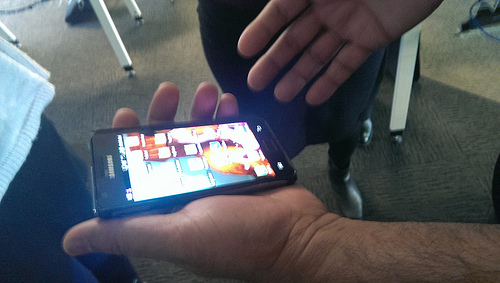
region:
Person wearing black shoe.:
[313, 148, 371, 228]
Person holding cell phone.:
[86, 110, 268, 218]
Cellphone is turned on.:
[84, 102, 281, 191]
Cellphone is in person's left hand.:
[95, 125, 284, 216]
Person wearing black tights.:
[331, 128, 355, 181]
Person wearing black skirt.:
[249, 58, 379, 126]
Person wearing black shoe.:
[357, 112, 381, 142]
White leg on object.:
[67, 18, 138, 80]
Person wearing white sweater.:
[6, 53, 65, 165]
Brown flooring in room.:
[47, 58, 147, 135]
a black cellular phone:
[91, 115, 296, 215]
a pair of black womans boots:
[327, 155, 365, 222]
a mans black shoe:
[357, 116, 373, 147]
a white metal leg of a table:
[89, 0, 142, 77]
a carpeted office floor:
[417, 63, 497, 216]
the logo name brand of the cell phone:
[104, 152, 116, 182]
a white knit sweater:
[0, 34, 53, 202]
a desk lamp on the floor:
[457, 0, 499, 40]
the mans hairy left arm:
[313, 215, 499, 281]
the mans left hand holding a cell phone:
[63, 81, 323, 281]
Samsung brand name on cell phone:
[101, 150, 116, 181]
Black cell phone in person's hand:
[81, 117, 298, 224]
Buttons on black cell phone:
[249, 119, 290, 171]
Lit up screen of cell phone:
[113, 119, 280, 201]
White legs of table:
[0, 0, 167, 83]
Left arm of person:
[300, 184, 498, 279]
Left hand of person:
[50, 76, 334, 276]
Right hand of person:
[240, 0, 454, 108]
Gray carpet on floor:
[177, 53, 498, 246]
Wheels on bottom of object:
[327, 103, 389, 226]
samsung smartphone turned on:
[87, 108, 300, 218]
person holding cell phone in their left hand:
[59, 79, 303, 264]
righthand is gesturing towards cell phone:
[86, 0, 447, 224]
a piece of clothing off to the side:
[0, 28, 58, 216]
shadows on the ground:
[41, 0, 192, 142]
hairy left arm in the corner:
[310, 215, 499, 282]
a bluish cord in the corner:
[463, 0, 498, 45]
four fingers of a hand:
[237, 0, 374, 107]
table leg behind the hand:
[385, 22, 423, 151]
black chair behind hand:
[198, 0, 395, 222]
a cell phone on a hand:
[57, 77, 318, 282]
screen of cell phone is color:
[111, 120, 271, 206]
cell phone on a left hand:
[50, 0, 498, 270]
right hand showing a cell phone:
[111, 83, 242, 131]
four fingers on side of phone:
[106, 78, 246, 133]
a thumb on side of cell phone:
[59, 214, 175, 269]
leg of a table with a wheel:
[381, 35, 423, 160]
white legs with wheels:
[3, 0, 156, 78]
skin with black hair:
[311, 208, 498, 279]